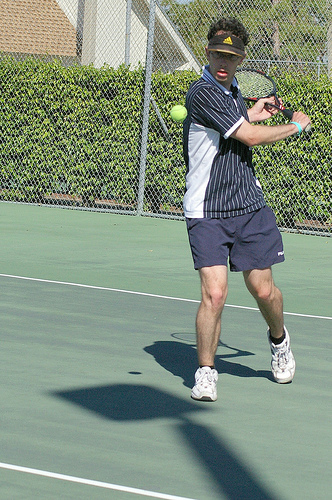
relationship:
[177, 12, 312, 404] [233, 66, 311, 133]
man swinging racket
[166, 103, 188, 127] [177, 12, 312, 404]
tennis ball near man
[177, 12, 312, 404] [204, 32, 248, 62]
man wearing visor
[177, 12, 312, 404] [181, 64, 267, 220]
man wearing shirt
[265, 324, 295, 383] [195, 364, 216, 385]
shoe has laces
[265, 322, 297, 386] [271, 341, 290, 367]
shoe has laces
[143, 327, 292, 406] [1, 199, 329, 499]
shadow on court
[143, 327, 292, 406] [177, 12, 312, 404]
shadow of man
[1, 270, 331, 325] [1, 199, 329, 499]
line on court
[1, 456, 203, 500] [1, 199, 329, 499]
line on court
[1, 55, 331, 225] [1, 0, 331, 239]
bush hedge behind fence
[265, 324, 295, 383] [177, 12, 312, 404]
shoe on foot of man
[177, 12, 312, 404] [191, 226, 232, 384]
man has leg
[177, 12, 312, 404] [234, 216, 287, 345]
man has leg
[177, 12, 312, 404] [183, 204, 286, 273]
man wearing shorts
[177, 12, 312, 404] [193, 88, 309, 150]
man has arm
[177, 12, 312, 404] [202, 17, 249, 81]
man has head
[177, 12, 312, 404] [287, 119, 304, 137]
man wearing bracelet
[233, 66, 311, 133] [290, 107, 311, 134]
racket held by hand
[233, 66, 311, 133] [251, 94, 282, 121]
racket held by hand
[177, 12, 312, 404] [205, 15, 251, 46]
man has hair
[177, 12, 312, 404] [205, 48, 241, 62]
man wearing glasses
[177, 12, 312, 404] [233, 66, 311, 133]
man holding racket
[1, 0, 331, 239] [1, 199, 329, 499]
fence surrounding court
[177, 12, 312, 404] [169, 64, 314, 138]
man playing tennis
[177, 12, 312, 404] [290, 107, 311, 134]
man has hand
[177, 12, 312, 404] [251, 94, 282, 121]
man has hand